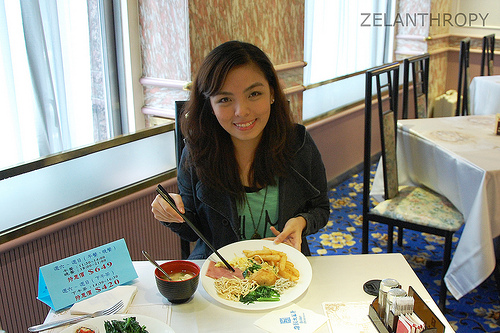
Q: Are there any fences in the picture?
A: No, there are no fences.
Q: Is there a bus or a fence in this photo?
A: No, there are no fences or buses.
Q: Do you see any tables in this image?
A: Yes, there is a table.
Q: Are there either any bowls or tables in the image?
A: Yes, there is a table.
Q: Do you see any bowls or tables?
A: Yes, there is a table.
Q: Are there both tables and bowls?
A: Yes, there are both a table and a bowl.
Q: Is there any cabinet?
A: No, there are no cabinets.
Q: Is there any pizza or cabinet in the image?
A: No, there are no cabinets or pizzas.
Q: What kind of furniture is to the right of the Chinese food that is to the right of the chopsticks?
A: The piece of furniture is a table.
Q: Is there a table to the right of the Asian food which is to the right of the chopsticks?
A: Yes, there is a table to the right of the Chinese food.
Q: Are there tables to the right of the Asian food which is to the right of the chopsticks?
A: Yes, there is a table to the right of the Chinese food.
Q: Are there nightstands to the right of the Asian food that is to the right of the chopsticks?
A: No, there is a table to the right of the Asian food.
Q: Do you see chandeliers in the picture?
A: No, there are no chandeliers.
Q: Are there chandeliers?
A: No, there are no chandeliers.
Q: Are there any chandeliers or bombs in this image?
A: No, there are no chandeliers or bombs.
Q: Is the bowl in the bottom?
A: Yes, the bowl is in the bottom of the image.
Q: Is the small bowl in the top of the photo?
A: No, the bowl is in the bottom of the image.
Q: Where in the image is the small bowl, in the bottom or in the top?
A: The bowl is in the bottom of the image.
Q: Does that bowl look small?
A: Yes, the bowl is small.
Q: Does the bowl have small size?
A: Yes, the bowl is small.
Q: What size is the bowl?
A: The bowl is small.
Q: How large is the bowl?
A: The bowl is small.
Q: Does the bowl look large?
A: No, the bowl is small.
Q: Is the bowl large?
A: No, the bowl is small.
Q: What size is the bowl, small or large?
A: The bowl is small.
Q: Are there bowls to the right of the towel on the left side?
A: Yes, there is a bowl to the right of the towel.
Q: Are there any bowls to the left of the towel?
A: No, the bowl is to the right of the towel.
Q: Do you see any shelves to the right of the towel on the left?
A: No, there is a bowl to the right of the towel.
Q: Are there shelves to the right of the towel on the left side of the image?
A: No, there is a bowl to the right of the towel.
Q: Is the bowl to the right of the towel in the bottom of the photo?
A: Yes, the bowl is to the right of the towel.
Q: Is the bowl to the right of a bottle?
A: No, the bowl is to the right of the towel.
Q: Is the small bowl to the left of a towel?
A: No, the bowl is to the right of a towel.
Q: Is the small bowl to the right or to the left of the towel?
A: The bowl is to the right of the towel.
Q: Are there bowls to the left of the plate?
A: Yes, there is a bowl to the left of the plate.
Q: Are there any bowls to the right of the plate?
A: No, the bowl is to the left of the plate.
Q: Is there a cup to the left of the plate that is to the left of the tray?
A: No, there is a bowl to the left of the plate.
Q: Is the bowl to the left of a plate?
A: Yes, the bowl is to the left of a plate.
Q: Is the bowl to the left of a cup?
A: No, the bowl is to the left of a plate.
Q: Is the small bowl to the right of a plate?
A: No, the bowl is to the left of a plate.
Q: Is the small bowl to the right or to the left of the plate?
A: The bowl is to the left of the plate.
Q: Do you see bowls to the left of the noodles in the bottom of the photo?
A: Yes, there is a bowl to the left of the noodles.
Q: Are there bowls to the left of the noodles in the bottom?
A: Yes, there is a bowl to the left of the noodles.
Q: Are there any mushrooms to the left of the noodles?
A: No, there is a bowl to the left of the noodles.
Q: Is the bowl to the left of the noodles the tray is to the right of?
A: Yes, the bowl is to the left of the noodles.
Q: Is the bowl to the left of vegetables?
A: No, the bowl is to the left of the noodles.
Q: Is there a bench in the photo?
A: No, there are no benches.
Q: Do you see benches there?
A: No, there are no benches.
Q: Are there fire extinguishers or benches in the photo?
A: No, there are no benches or fire extinguishers.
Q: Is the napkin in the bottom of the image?
A: Yes, the napkin is in the bottom of the image.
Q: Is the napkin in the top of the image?
A: No, the napkin is in the bottom of the image.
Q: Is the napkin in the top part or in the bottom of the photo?
A: The napkin is in the bottom of the image.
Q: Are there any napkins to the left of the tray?
A: Yes, there is a napkin to the left of the tray.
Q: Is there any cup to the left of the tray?
A: No, there is a napkin to the left of the tray.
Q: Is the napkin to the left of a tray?
A: Yes, the napkin is to the left of a tray.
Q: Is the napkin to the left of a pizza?
A: No, the napkin is to the left of a tray.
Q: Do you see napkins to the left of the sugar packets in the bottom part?
A: Yes, there is a napkin to the left of the sugar packets.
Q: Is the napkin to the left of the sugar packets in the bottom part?
A: Yes, the napkin is to the left of the sugar packets.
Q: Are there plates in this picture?
A: Yes, there is a plate.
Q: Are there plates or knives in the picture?
A: Yes, there is a plate.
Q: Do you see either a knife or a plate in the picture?
A: Yes, there is a plate.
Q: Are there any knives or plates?
A: Yes, there is a plate.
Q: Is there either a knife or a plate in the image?
A: Yes, there is a plate.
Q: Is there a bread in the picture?
A: No, there is no breads.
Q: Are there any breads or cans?
A: No, there are no breads or cans.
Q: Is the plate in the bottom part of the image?
A: Yes, the plate is in the bottom of the image.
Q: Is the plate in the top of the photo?
A: No, the plate is in the bottom of the image.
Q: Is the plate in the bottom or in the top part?
A: The plate is in the bottom of the image.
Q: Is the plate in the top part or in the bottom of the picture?
A: The plate is in the bottom of the image.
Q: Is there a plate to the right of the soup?
A: Yes, there is a plate to the right of the soup.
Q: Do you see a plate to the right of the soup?
A: Yes, there is a plate to the right of the soup.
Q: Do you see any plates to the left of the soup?
A: No, the plate is to the right of the soup.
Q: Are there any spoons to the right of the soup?
A: No, there is a plate to the right of the soup.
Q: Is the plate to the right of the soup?
A: Yes, the plate is to the right of the soup.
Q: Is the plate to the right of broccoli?
A: No, the plate is to the right of the soup.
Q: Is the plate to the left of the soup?
A: No, the plate is to the right of the soup.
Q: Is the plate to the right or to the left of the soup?
A: The plate is to the right of the soup.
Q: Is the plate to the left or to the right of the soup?
A: The plate is to the right of the soup.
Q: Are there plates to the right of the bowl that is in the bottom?
A: Yes, there is a plate to the right of the bowl.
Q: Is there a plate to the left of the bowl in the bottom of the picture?
A: No, the plate is to the right of the bowl.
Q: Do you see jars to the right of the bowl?
A: No, there is a plate to the right of the bowl.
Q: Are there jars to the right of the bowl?
A: No, there is a plate to the right of the bowl.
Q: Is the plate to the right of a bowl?
A: Yes, the plate is to the right of a bowl.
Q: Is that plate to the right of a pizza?
A: No, the plate is to the right of a bowl.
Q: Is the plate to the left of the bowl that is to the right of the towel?
A: No, the plate is to the right of the bowl.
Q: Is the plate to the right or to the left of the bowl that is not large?
A: The plate is to the right of the bowl.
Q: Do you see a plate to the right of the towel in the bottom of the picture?
A: Yes, there is a plate to the right of the towel.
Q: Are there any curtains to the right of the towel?
A: No, there is a plate to the right of the towel.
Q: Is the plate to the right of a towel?
A: Yes, the plate is to the right of a towel.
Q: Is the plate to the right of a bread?
A: No, the plate is to the right of a towel.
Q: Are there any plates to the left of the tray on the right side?
A: Yes, there is a plate to the left of the tray.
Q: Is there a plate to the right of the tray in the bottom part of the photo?
A: No, the plate is to the left of the tray.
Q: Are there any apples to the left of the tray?
A: No, there is a plate to the left of the tray.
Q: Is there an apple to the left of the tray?
A: No, there is a plate to the left of the tray.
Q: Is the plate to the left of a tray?
A: Yes, the plate is to the left of a tray.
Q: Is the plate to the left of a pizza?
A: No, the plate is to the left of a tray.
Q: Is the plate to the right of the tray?
A: No, the plate is to the left of the tray.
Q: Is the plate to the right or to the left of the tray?
A: The plate is to the left of the tray.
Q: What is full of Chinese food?
A: The plate is full of Chinese food.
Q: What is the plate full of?
A: The plate is full of Chinese food.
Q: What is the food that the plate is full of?
A: The food is Chinese food.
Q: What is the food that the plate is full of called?
A: The food is Chinese food.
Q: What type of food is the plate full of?
A: The plate is full of Chinese food.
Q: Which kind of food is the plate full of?
A: The plate is full of Chinese food.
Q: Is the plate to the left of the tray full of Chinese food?
A: Yes, the plate is full of Chinese food.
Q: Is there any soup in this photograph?
A: Yes, there is soup.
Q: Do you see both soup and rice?
A: No, there is soup but no rice.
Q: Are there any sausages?
A: No, there are no sausages.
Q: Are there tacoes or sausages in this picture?
A: No, there are no sausages or tacoes.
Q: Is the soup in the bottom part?
A: Yes, the soup is in the bottom of the image.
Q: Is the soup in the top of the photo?
A: No, the soup is in the bottom of the image.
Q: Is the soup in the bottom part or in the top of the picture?
A: The soup is in the bottom of the image.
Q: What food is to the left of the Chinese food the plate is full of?
A: The food is soup.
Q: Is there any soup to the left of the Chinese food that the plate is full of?
A: Yes, there is soup to the left of the Asian food.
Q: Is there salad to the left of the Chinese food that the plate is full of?
A: No, there is soup to the left of the Chinese food.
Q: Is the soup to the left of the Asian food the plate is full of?
A: Yes, the soup is to the left of the Chinese food.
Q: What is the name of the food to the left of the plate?
A: The food is soup.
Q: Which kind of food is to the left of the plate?
A: The food is soup.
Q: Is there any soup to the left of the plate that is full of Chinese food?
A: Yes, there is soup to the left of the plate.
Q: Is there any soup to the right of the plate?
A: No, the soup is to the left of the plate.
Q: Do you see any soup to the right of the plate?
A: No, the soup is to the left of the plate.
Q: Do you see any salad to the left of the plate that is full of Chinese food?
A: No, there is soup to the left of the plate.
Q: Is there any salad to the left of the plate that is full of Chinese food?
A: No, there is soup to the left of the plate.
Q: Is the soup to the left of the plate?
A: Yes, the soup is to the left of the plate.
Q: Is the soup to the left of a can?
A: No, the soup is to the left of the plate.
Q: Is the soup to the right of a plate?
A: No, the soup is to the left of a plate.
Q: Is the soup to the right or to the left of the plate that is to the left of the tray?
A: The soup is to the left of the plate.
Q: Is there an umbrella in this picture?
A: No, there are no umbrellas.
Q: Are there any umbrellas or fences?
A: No, there are no umbrellas or fences.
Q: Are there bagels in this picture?
A: No, there are no bagels.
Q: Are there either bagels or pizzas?
A: No, there are no bagels or pizzas.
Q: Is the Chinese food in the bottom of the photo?
A: Yes, the Chinese food is in the bottom of the image.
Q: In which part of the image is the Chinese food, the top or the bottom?
A: The Chinese food is in the bottom of the image.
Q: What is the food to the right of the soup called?
A: The food is Chinese food.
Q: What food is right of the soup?
A: The food is Chinese food.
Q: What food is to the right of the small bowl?
A: The food is Chinese food.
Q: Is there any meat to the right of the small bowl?
A: No, there is Chinese food to the right of the bowl.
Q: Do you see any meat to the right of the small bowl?
A: No, there is Chinese food to the right of the bowl.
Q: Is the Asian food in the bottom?
A: Yes, the Asian food is in the bottom of the image.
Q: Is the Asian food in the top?
A: No, the Asian food is in the bottom of the image.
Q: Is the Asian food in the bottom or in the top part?
A: The Asian food is in the bottom of the image.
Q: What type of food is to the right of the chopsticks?
A: The food is Chinese food.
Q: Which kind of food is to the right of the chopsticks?
A: The food is Chinese food.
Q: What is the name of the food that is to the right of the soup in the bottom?
A: The food is Chinese food.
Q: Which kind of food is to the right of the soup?
A: The food is Chinese food.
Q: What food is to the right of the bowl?
A: The food is Chinese food.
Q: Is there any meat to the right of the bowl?
A: No, there is Chinese food to the right of the bowl.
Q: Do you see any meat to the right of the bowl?
A: No, there is Chinese food to the right of the bowl.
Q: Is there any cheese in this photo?
A: No, there is no cheese.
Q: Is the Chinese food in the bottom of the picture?
A: Yes, the Chinese food is in the bottom of the image.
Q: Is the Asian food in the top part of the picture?
A: No, the Asian food is in the bottom of the image.